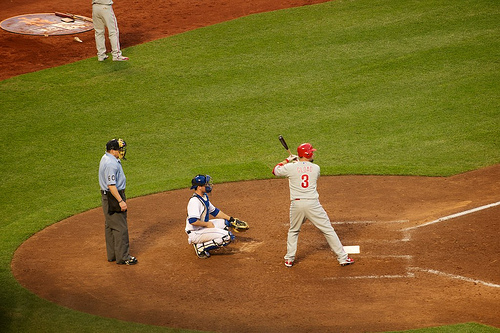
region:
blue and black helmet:
[182, 165, 218, 215]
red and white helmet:
[285, 125, 326, 171]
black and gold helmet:
[102, 130, 139, 160]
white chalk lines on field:
[360, 192, 495, 314]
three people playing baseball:
[0, 134, 337, 276]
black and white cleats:
[100, 252, 140, 288]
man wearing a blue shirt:
[76, 145, 138, 201]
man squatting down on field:
[144, 142, 245, 299]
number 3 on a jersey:
[287, 170, 314, 192]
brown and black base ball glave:
[220, 211, 265, 265]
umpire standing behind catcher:
[102, 140, 135, 265]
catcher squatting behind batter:
[185, 173, 246, 253]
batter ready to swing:
[270, 130, 352, 273]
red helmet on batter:
[297, 145, 314, 155]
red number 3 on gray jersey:
[300, 175, 307, 190]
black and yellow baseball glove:
[228, 215, 246, 229]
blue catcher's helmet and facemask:
[189, 175, 211, 195]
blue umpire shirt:
[100, 155, 125, 191]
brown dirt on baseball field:
[10, 170, 496, 325]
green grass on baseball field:
[2, 2, 495, 189]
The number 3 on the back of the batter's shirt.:
[297, 172, 312, 187]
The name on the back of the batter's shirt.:
[294, 165, 315, 177]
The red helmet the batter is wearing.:
[298, 138, 315, 155]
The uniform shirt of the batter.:
[277, 161, 324, 197]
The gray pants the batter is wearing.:
[290, 195, 351, 263]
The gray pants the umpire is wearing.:
[105, 194, 142, 247]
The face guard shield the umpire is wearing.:
[111, 130, 126, 156]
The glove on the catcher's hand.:
[229, 212, 249, 237]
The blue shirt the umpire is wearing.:
[102, 155, 126, 191]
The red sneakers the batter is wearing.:
[284, 251, 362, 273]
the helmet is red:
[281, 88, 359, 168]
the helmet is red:
[261, 126, 362, 247]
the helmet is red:
[233, 61, 386, 312]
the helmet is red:
[245, 150, 336, 321]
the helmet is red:
[302, 123, 392, 328]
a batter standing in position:
[257, 123, 367, 290]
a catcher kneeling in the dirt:
[160, 152, 266, 284]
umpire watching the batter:
[82, 130, 149, 269]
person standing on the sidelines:
[72, 0, 144, 68]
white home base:
[325, 225, 376, 262]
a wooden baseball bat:
[269, 127, 296, 169]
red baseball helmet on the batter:
[287, 132, 319, 164]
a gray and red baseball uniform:
[266, 157, 348, 204]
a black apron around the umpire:
[99, 178, 135, 213]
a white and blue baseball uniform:
[172, 160, 255, 267]